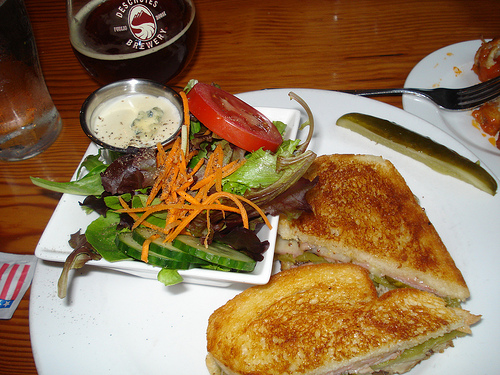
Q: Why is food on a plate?
A: To be eaten.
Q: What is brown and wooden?
A: Table.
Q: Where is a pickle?
A: On the plate.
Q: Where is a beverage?
A: In a glass.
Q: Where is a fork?
A: On small plate.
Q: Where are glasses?
A: On the table.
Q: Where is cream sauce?
A: In round container.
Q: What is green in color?
A: Cucumber slices.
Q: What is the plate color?
A: White.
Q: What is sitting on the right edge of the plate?
A: Pickle slice.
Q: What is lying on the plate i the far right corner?
A: A fork.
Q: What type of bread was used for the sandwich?
A: Toasted bread.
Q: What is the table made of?
A: Wood.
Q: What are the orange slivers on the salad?
A: Carrots.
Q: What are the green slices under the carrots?
A: Cucumber.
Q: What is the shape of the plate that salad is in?
A: Square.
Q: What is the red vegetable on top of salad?
A: Tomato.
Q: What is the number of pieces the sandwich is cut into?
A: Two.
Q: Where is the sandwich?
A: On the plate.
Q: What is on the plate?
A: Food.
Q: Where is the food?
A: On the plate.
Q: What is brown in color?
A: The sandwich.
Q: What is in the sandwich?
A: Food.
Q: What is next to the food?
A: Salad.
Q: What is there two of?
A: Sandwiches.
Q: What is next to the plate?
A: A glass.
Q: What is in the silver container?
A: Salad dressing.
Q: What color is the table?
A: Brown.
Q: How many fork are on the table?
A: 1.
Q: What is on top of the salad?
A: Carrots.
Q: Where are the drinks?
A: On the table.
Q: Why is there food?
A: To eat.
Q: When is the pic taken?
A: Lunch time.